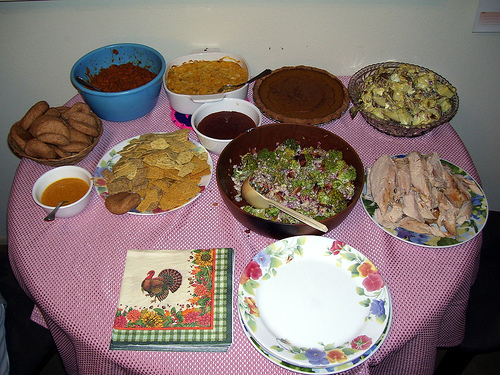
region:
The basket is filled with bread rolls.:
[4, 98, 105, 168]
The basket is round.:
[3, 98, 104, 173]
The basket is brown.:
[5, 99, 107, 172]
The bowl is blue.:
[69, 38, 165, 136]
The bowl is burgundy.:
[211, 117, 363, 245]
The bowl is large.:
[211, 118, 368, 245]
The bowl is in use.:
[209, 117, 365, 245]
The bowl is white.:
[188, 93, 264, 165]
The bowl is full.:
[187, 93, 267, 163]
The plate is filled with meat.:
[356, 144, 490, 254]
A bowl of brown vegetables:
[7, 98, 104, 163]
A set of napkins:
[110, 249, 233, 349]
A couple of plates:
[237, 234, 396, 374]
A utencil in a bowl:
[240, 172, 328, 232]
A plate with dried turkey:
[362, 150, 491, 245]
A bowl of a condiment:
[31, 165, 91, 219]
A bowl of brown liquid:
[190, 98, 262, 149]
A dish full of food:
[347, 61, 459, 135]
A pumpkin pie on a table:
[251, 65, 349, 122]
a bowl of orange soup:
[164, 47, 251, 112]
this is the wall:
[186, 0, 311, 50]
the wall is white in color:
[351, 12, 418, 43]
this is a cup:
[33, 179, 91, 211]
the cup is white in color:
[67, 203, 87, 212]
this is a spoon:
[43, 195, 63, 227]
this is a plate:
[283, 254, 369, 347]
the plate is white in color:
[288, 290, 345, 333]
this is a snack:
[106, 186, 149, 222]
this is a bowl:
[101, 87, 160, 115]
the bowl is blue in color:
[110, 90, 149, 116]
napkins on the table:
[119, 249, 233, 343]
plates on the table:
[245, 243, 386, 373]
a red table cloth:
[40, 105, 420, 358]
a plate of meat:
[374, 157, 480, 240]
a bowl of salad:
[226, 126, 353, 232]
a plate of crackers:
[104, 139, 196, 211]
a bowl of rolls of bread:
[16, 95, 96, 161]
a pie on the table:
[261, 68, 343, 122]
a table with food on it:
[16, 45, 463, 373]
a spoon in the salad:
[241, 175, 335, 235]